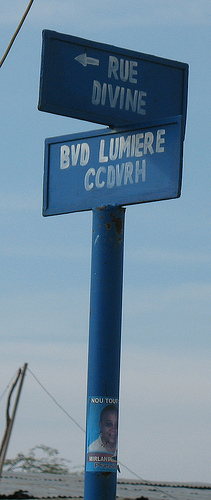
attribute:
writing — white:
[59, 52, 164, 190]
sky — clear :
[1, 1, 209, 481]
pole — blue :
[93, 358, 118, 393]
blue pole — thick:
[83, 206, 125, 496]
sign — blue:
[26, 30, 192, 171]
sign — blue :
[34, 21, 191, 142]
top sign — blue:
[37, 28, 187, 138]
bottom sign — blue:
[42, 114, 183, 216]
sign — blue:
[41, 112, 183, 216]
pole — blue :
[80, 204, 126, 499]